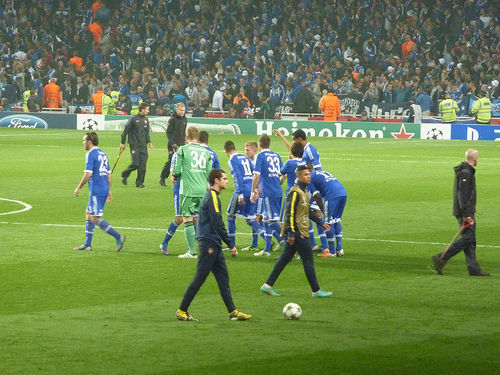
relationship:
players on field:
[83, 108, 354, 323] [3, 139, 497, 374]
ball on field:
[283, 304, 303, 319] [3, 139, 497, 374]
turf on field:
[8, 127, 78, 240] [3, 139, 497, 374]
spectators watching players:
[6, 1, 497, 108] [83, 108, 354, 323]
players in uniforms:
[83, 108, 354, 323] [227, 144, 352, 261]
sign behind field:
[111, 117, 421, 141] [3, 139, 497, 374]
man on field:
[437, 139, 487, 282] [3, 139, 497, 374]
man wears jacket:
[437, 139, 487, 282] [450, 158, 472, 218]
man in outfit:
[262, 168, 332, 299] [270, 190, 323, 292]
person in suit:
[317, 90, 340, 124] [316, 97, 342, 119]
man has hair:
[262, 168, 332, 299] [298, 165, 307, 174]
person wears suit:
[317, 90, 340, 124] [316, 97, 342, 119]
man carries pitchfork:
[437, 139, 487, 282] [424, 216, 471, 276]